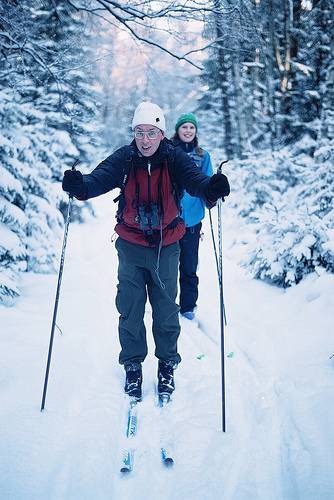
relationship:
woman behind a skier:
[168, 113, 219, 320] [61, 101, 231, 398]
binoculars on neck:
[120, 196, 158, 234] [134, 145, 168, 160]